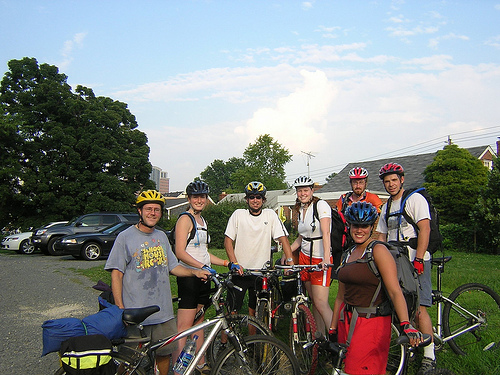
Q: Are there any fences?
A: No, there are no fences.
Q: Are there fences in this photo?
A: No, there are no fences.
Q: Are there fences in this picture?
A: No, there are no fences.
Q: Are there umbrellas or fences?
A: No, there are no fences or umbrellas.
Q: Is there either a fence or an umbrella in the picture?
A: No, there are no fences or umbrellas.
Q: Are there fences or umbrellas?
A: No, there are no fences or umbrellas.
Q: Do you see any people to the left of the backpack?
A: Yes, there are people to the left of the backpack.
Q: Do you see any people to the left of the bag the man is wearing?
A: Yes, there are people to the left of the backpack.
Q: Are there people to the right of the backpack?
A: No, the people are to the left of the backpack.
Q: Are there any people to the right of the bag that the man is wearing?
A: No, the people are to the left of the backpack.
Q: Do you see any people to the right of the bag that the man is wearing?
A: No, the people are to the left of the backpack.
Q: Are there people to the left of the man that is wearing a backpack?
A: Yes, there are people to the left of the man.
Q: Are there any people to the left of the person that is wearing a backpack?
A: Yes, there are people to the left of the man.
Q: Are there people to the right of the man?
A: No, the people are to the left of the man.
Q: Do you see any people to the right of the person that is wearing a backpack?
A: No, the people are to the left of the man.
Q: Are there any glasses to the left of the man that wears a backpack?
A: No, there are people to the left of the man.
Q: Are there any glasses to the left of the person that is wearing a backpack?
A: No, there are people to the left of the man.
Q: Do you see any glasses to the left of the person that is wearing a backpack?
A: No, there are people to the left of the man.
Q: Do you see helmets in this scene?
A: Yes, there is a helmet.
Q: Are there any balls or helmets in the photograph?
A: Yes, there is a helmet.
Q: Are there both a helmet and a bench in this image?
A: No, there is a helmet but no benches.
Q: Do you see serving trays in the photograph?
A: No, there are no serving trays.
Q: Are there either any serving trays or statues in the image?
A: No, there are no serving trays or statues.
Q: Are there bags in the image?
A: Yes, there is a bag.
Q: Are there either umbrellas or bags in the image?
A: Yes, there is a bag.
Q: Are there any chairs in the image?
A: No, there are no chairs.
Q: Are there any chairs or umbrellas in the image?
A: No, there are no chairs or umbrellas.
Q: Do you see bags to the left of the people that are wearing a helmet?
A: Yes, there is a bag to the left of the people.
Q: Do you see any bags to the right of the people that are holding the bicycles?
A: No, the bag is to the left of the people.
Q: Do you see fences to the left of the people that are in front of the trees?
A: No, there is a bag to the left of the people.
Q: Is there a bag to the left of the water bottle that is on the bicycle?
A: Yes, there is a bag to the left of the water bottle.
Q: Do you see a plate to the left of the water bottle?
A: No, there is a bag to the left of the water bottle.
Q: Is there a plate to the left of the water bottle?
A: No, there is a bag to the left of the water bottle.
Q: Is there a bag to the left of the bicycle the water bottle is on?
A: Yes, there is a bag to the left of the bicycle.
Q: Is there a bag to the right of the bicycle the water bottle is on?
A: No, the bag is to the left of the bicycle.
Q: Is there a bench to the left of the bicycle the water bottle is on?
A: No, there is a bag to the left of the bicycle.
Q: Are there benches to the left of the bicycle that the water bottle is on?
A: No, there is a bag to the left of the bicycle.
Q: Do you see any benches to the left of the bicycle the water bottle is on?
A: No, there is a bag to the left of the bicycle.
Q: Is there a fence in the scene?
A: No, there are no fences.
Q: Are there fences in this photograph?
A: No, there are no fences.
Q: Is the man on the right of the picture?
A: Yes, the man is on the right of the image.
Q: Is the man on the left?
A: No, the man is on the right of the image.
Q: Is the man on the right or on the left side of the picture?
A: The man is on the right of the image.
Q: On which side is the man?
A: The man is on the right of the image.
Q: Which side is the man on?
A: The man is on the right of the image.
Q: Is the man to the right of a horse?
A: No, the man is to the right of the helmet.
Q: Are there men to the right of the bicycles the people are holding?
A: Yes, there is a man to the right of the bicycles.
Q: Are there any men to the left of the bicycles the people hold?
A: No, the man is to the right of the bicycles.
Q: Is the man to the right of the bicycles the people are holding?
A: Yes, the man is to the right of the bicycles.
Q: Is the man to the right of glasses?
A: No, the man is to the right of the bicycles.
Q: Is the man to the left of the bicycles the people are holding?
A: No, the man is to the right of the bicycles.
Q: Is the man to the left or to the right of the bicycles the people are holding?
A: The man is to the right of the bicycles.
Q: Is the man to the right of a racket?
A: No, the man is to the right of the helmet.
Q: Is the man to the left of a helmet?
A: No, the man is to the right of a helmet.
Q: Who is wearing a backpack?
A: The man is wearing a backpack.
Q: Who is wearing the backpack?
A: The man is wearing a backpack.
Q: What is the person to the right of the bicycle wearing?
A: The man is wearing a backpack.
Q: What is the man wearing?
A: The man is wearing a backpack.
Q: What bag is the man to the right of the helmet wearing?
A: The man is wearing a backpack.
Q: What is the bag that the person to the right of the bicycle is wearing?
A: The bag is a backpack.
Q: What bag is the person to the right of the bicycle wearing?
A: The man is wearing a backpack.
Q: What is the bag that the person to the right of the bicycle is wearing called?
A: The bag is a backpack.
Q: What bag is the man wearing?
A: The man is wearing a backpack.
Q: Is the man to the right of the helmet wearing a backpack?
A: Yes, the man is wearing a backpack.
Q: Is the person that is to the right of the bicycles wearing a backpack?
A: Yes, the man is wearing a backpack.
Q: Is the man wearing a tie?
A: No, the man is wearing a backpack.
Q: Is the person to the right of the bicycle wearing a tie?
A: No, the man is wearing a backpack.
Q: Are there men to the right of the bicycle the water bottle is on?
A: Yes, there is a man to the right of the bicycle.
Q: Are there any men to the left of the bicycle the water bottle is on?
A: No, the man is to the right of the bicycle.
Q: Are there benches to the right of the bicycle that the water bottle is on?
A: No, there is a man to the right of the bicycle.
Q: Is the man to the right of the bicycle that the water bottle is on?
A: Yes, the man is to the right of the bicycle.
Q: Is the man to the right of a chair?
A: No, the man is to the right of the bicycle.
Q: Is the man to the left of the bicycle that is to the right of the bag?
A: No, the man is to the right of the bicycle.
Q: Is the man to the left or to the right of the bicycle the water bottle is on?
A: The man is to the right of the bicycle.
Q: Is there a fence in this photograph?
A: No, there are no fences.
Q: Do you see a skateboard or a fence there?
A: No, there are no fences or skateboards.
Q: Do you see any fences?
A: No, there are no fences.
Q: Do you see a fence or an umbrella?
A: No, there are no fences or umbrellas.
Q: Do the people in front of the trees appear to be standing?
A: Yes, the people are standing.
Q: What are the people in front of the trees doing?
A: The people are standing.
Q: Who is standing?
A: The people are standing.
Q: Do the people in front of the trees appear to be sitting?
A: No, the people are standing.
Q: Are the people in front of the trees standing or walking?
A: The people are standing.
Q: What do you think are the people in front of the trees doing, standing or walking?
A: The people are standing.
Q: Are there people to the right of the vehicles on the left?
A: Yes, there are people to the right of the vehicles.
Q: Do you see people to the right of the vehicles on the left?
A: Yes, there are people to the right of the vehicles.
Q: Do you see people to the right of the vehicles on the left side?
A: Yes, there are people to the right of the vehicles.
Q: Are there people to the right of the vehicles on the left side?
A: Yes, there are people to the right of the vehicles.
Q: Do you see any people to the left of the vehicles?
A: No, the people are to the right of the vehicles.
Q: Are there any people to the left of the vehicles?
A: No, the people are to the right of the vehicles.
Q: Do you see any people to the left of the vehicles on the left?
A: No, the people are to the right of the vehicles.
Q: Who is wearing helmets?
A: The people are wearing helmets.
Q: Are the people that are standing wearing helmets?
A: Yes, the people are wearing helmets.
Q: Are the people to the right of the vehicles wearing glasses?
A: No, the people are wearing helmets.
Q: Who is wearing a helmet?
A: The people are wearing a helmet.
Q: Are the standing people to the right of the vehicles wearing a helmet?
A: Yes, the people are wearing a helmet.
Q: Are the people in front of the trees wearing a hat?
A: No, the people are wearing a helmet.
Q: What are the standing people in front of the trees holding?
A: The people are holding the bicycles.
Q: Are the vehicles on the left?
A: Yes, the vehicles are on the left of the image.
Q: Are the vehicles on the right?
A: No, the vehicles are on the left of the image.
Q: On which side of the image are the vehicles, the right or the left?
A: The vehicles are on the left of the image.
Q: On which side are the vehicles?
A: The vehicles are on the left of the image.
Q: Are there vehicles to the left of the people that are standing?
A: Yes, there are vehicles to the left of the people.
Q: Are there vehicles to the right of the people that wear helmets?
A: No, the vehicles are to the left of the people.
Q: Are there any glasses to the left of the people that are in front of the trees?
A: No, there are vehicles to the left of the people.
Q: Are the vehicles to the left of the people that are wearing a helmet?
A: Yes, the vehicles are to the left of the people.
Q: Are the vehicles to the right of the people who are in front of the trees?
A: No, the vehicles are to the left of the people.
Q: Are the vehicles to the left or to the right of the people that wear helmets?
A: The vehicles are to the left of the people.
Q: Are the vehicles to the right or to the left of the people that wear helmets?
A: The vehicles are to the left of the people.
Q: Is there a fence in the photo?
A: No, there are no fences.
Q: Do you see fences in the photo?
A: No, there are no fences.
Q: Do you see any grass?
A: Yes, there is grass.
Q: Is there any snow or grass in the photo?
A: Yes, there is grass.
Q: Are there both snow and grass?
A: No, there is grass but no snow.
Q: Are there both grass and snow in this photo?
A: No, there is grass but no snow.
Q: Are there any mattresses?
A: No, there are no mattresses.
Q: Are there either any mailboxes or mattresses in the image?
A: No, there are no mattresses or mailboxes.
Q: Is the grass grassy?
A: Yes, the grass is grassy.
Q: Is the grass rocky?
A: No, the grass is grassy.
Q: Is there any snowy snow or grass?
A: No, there is grass but it is grassy.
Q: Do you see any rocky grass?
A: No, there is grass but it is grassy.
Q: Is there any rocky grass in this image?
A: No, there is grass but it is grassy.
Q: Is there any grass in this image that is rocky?
A: No, there is grass but it is grassy.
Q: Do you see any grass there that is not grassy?
A: No, there is grass but it is grassy.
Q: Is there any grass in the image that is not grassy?
A: No, there is grass but it is grassy.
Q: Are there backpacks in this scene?
A: Yes, there is a backpack.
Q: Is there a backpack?
A: Yes, there is a backpack.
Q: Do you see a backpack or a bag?
A: Yes, there is a backpack.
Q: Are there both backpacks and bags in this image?
A: Yes, there are both a backpack and a bag.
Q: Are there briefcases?
A: No, there are no briefcases.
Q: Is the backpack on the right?
A: Yes, the backpack is on the right of the image.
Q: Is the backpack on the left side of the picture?
A: No, the backpack is on the right of the image.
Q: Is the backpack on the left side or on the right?
A: The backpack is on the right of the image.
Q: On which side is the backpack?
A: The backpack is on the right of the image.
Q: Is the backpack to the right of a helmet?
A: Yes, the backpack is to the right of a helmet.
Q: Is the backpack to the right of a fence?
A: No, the backpack is to the right of a helmet.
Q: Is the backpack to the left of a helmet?
A: No, the backpack is to the right of a helmet.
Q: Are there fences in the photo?
A: No, there are no fences.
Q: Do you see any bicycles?
A: Yes, there are bicycles.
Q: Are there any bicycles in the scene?
A: Yes, there are bicycles.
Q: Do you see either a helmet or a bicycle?
A: Yes, there are bicycles.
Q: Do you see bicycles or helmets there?
A: Yes, there are bicycles.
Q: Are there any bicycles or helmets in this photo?
A: Yes, there are bicycles.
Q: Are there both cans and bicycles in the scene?
A: No, there are bicycles but no cans.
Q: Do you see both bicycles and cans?
A: No, there are bicycles but no cans.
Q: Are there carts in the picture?
A: No, there are no carts.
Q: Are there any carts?
A: No, there are no carts.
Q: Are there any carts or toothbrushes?
A: No, there are no carts or toothbrushes.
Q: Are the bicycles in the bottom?
A: Yes, the bicycles are in the bottom of the image.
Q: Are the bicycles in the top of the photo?
A: No, the bicycles are in the bottom of the image.